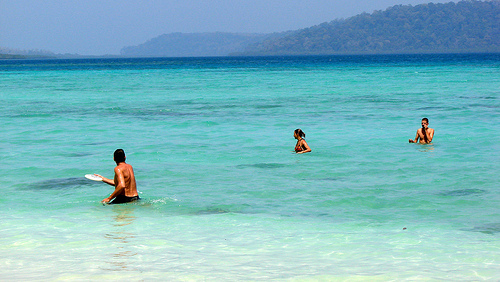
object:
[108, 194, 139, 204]
trunks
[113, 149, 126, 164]
head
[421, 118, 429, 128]
head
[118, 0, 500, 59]
slope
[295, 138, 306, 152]
bathing suit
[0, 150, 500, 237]
shapes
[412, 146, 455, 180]
ground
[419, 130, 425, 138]
chest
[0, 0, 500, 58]
blue sky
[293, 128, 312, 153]
person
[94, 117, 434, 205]
people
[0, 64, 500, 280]
ocean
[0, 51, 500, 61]
horizon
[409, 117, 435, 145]
man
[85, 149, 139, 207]
man